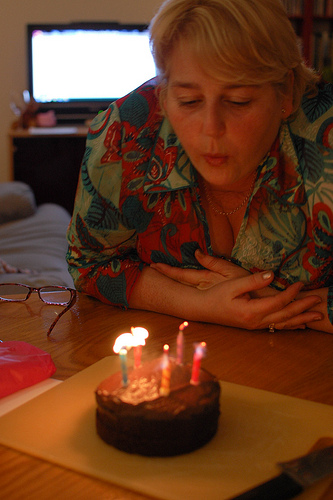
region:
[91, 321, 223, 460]
Chocolate birthday cake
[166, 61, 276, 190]
woman blowing out candles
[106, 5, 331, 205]
Woman in green and red blouse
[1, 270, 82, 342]
reading glasses on table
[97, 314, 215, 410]
half blown birthday candles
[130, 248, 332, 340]
A woman's hands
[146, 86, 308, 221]
woman wearing necklace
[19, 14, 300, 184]
woman with wide screen TV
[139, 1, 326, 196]
Blonde haired woman wearing earing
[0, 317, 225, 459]
Birthday cake and red tissue paper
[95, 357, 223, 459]
a small chocolate cake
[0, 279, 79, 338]
part of a woman's' eyeglasses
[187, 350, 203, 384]
a skinny red candle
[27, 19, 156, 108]
part of a black t.v.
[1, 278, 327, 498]
a large brown table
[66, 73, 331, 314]
a woman's colorful shirt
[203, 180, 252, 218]
part of a woman's necklace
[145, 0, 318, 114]
part of a woman's blonde hair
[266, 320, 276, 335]
part of a woman's ring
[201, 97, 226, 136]
the nose of a woman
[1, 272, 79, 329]
red and black reading glasses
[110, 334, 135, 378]
lit blue birthday candle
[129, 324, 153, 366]
lit orange birthday candle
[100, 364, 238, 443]
small chocolate birthday cake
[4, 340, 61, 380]
red wrapped birthday gift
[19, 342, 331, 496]
white square plate with cake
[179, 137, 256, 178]
woman blowing out candles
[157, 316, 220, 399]
three blown out candles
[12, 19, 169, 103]
lit up tv in background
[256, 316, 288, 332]
ring on woman's right hand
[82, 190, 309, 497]
a small round cake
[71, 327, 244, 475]
a round chocolate cake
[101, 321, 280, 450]
a small round chocolate cake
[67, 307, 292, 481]
a cake with candles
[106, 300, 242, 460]
a cake with lit candles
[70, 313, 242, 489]
a small cake with candles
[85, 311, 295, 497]
a small cake with lit candles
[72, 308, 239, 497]
a round cake with candles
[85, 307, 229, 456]
a round cake with lit candles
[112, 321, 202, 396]
colorful candles on a cake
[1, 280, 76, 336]
a pair of glasses on a table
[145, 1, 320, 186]
a woman blowing candles on a cake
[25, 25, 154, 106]
a turned on TV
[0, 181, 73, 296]
a gray couch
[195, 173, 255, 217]
woman wearing a silver chain around her neck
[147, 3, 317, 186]
a woman with short blonde hair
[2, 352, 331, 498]
a cake on a cutting board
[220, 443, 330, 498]
a black knife on a cutting board